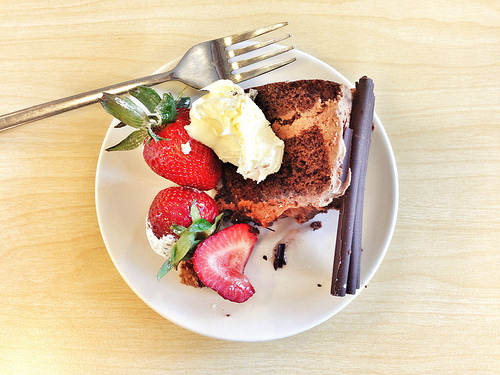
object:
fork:
[0, 17, 299, 137]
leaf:
[99, 89, 153, 132]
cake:
[204, 75, 356, 232]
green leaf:
[170, 219, 194, 241]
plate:
[85, 33, 401, 347]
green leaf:
[185, 203, 203, 228]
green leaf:
[102, 127, 153, 155]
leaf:
[155, 92, 177, 122]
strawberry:
[142, 109, 221, 190]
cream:
[177, 76, 288, 183]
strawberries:
[189, 222, 265, 305]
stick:
[327, 75, 380, 301]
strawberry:
[145, 187, 225, 263]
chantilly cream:
[145, 222, 178, 258]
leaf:
[124, 83, 176, 120]